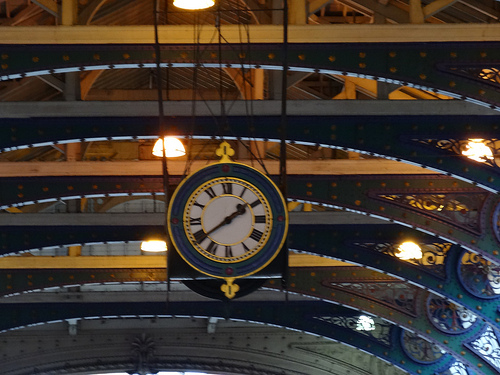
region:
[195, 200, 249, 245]
black hand of a clock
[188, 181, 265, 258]
white face of clock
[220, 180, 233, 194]
black roman numeral 12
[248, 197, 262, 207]
black roman numeral 2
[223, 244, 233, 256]
black roman numeral 6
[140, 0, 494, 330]
six lights are on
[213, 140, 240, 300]
two ornate gold decorations on clock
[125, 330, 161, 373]
decoration on entrance arch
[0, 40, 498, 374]
decorative bands on ceiling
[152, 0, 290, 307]
black metal supports for clock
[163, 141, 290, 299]
clock hanging from arched ceiling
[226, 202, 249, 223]
hour hand of clock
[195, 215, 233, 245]
minute hand of clock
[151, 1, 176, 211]
hanger rod of clock suspended from ceiling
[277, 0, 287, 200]
hanger rod of clock suspended from ceiling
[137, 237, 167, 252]
light hung below ceiling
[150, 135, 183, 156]
light hung below ceiling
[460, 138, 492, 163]
light hung below ceiling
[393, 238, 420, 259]
light hung below ceiling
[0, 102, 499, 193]
arch supporting the ceiling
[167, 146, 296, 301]
clock is hanging from the ceiling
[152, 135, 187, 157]
light is hanging from the ceiling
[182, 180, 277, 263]
the clock has roman numerals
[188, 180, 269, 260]
the clock has white clockface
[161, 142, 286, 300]
the clock has gold ornamentation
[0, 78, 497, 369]
the ceiling has arches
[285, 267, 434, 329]
the ceiling supports are made of steel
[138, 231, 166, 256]
the ceiling light is on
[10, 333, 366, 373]
the arch is ornamented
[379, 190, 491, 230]
ornamental design on ceiling support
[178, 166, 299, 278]
the clock is has yellow frame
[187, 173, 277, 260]
the clock has roman numbers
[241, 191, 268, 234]
the roman numbers are black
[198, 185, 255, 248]
the clock handles are black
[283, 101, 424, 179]
the frame is mettalic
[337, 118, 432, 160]
the frame is blue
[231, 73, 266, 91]
the frame is made of wood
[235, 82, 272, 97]
the frame is brown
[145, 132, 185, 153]
the light bulb is yellow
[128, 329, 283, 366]
the frame is grey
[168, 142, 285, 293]
ornate railway station clock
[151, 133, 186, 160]
domed ceiling light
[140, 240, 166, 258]
domed ceiling light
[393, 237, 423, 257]
domed ceiling light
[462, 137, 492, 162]
domed ceiling light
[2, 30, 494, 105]
decorative arch ceiling supports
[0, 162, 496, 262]
decorative arch ceiling supports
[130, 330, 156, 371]
ornate artwork on iron beam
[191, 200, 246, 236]
black hour and minute hand of clock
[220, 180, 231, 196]
roman numeral 12 on clock face